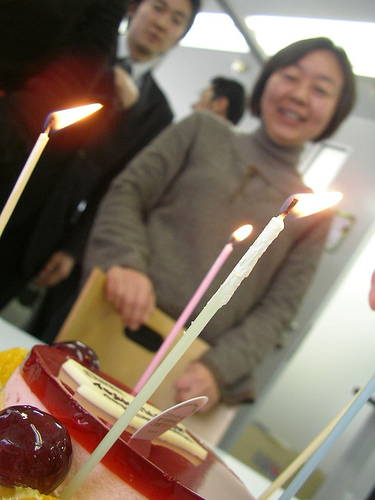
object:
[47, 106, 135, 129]
fire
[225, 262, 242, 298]
candle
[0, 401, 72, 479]
cherry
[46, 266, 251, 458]
chair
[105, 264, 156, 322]
hand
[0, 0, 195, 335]
man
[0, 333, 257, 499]
cake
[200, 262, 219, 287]
candles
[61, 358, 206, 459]
jello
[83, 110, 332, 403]
shirt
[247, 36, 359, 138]
hair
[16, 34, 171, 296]
suit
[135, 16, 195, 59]
head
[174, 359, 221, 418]
hands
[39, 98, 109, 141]
flame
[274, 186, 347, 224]
flames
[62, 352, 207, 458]
dessert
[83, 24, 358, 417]
people